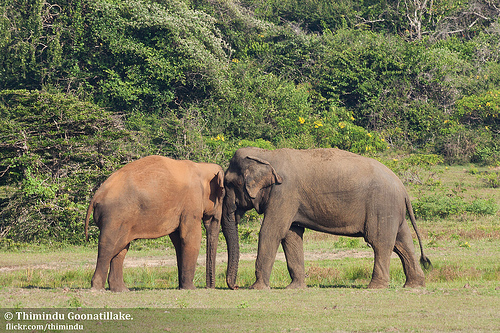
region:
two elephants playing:
[48, 144, 438, 296]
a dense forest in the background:
[3, 4, 494, 116]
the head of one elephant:
[228, 149, 275, 214]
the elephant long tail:
[400, 191, 441, 271]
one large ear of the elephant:
[243, 154, 280, 201]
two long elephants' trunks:
[205, 218, 238, 291]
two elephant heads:
[198, 146, 271, 213]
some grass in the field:
[141, 302, 325, 329]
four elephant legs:
[260, 219, 421, 301]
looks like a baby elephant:
[86, 149, 221, 294]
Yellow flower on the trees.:
[295, 110, 309, 130]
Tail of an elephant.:
[402, 197, 432, 269]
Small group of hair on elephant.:
[416, 253, 434, 269]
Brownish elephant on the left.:
[79, 130, 226, 287]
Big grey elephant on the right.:
[219, 151, 424, 293]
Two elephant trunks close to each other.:
[206, 213, 244, 295]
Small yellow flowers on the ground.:
[458, 239, 472, 250]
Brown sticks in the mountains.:
[41, 105, 131, 149]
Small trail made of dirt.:
[0, 250, 68, 270]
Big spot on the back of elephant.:
[307, 145, 338, 162]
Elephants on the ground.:
[71, 93, 498, 304]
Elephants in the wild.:
[47, 105, 498, 310]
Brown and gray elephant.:
[36, 94, 482, 311]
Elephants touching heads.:
[171, 122, 296, 240]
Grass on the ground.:
[34, 240, 243, 314]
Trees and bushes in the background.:
[113, 13, 388, 185]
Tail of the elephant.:
[386, 186, 446, 279]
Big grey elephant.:
[214, 123, 475, 324]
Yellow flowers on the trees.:
[230, 87, 363, 147]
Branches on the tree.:
[375, 3, 459, 54]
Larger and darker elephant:
[221, 149, 432, 289]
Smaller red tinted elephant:
[82, 154, 222, 290]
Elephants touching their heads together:
[83, 145, 430, 288]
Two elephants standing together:
[82, 147, 428, 288]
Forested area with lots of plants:
[2, 0, 498, 237]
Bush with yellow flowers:
[203, 99, 396, 150]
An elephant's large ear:
[241, 157, 281, 197]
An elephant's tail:
[403, 195, 436, 272]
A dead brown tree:
[356, 0, 499, 42]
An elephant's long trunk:
[223, 171, 240, 287]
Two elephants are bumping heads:
[73, 146, 443, 298]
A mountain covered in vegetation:
[5, 0, 499, 145]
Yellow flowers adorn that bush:
[280, 110, 382, 144]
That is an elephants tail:
[66, 160, 103, 252]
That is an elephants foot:
[248, 264, 278, 295]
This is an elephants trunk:
[220, 212, 249, 289]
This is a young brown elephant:
[69, 131, 225, 297]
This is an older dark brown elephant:
[226, 143, 436, 300]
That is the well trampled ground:
[2, 249, 494, 326]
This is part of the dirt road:
[4, 258, 95, 270]